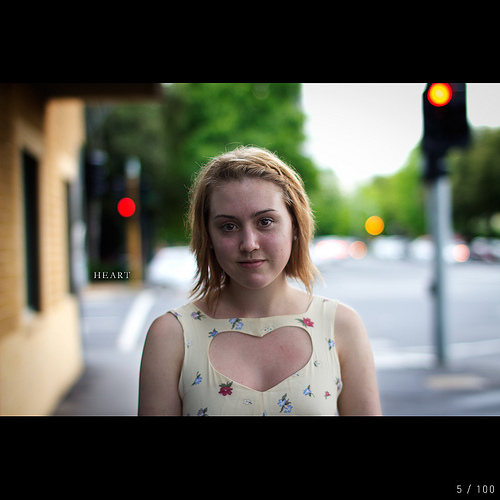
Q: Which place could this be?
A: It is a street.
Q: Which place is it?
A: It is a street.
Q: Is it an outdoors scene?
A: Yes, it is outdoors.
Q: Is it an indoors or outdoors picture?
A: It is outdoors.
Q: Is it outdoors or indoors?
A: It is outdoors.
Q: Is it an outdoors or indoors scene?
A: It is outdoors.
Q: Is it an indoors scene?
A: No, it is outdoors.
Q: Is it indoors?
A: No, it is outdoors.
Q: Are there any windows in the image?
A: Yes, there is a window.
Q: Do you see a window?
A: Yes, there is a window.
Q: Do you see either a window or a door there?
A: Yes, there is a window.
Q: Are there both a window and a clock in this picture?
A: No, there is a window but no clocks.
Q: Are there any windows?
A: Yes, there is a window.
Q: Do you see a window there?
A: Yes, there is a window.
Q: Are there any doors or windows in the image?
A: Yes, there is a window.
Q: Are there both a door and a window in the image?
A: No, there is a window but no doors.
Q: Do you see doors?
A: No, there are no doors.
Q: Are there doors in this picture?
A: No, there are no doors.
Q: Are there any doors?
A: No, there are no doors.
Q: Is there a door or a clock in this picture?
A: No, there are no doors or clocks.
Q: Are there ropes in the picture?
A: No, there are no ropes.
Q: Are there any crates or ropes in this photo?
A: No, there are no ropes or crates.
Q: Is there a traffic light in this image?
A: Yes, there is a traffic light.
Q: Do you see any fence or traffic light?
A: Yes, there is a traffic light.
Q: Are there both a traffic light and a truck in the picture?
A: No, there is a traffic light but no trucks.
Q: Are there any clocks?
A: No, there are no clocks.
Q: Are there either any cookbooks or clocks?
A: No, there are no clocks or cookbooks.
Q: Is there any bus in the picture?
A: No, there are no buses.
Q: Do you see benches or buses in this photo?
A: No, there are no buses or benches.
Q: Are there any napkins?
A: No, there are no napkins.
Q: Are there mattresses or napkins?
A: No, there are no napkins or mattresses.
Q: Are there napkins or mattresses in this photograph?
A: No, there are no napkins or mattresses.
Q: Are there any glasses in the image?
A: No, there are no glasses.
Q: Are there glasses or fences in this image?
A: No, there are no glasses or fences.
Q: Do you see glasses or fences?
A: No, there are no glasses or fences.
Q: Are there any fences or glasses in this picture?
A: No, there are no glasses or fences.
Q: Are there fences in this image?
A: No, there are no fences.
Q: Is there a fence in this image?
A: No, there are no fences.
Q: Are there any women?
A: Yes, there is a woman.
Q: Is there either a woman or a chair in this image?
A: Yes, there is a woman.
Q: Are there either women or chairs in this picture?
A: Yes, there is a woman.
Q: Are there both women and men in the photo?
A: No, there is a woman but no men.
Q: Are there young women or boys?
A: Yes, there is a young woman.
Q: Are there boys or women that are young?
A: Yes, the woman is young.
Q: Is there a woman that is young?
A: Yes, there is a young woman.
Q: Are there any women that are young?
A: Yes, there is a woman that is young.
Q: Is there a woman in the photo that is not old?
A: Yes, there is an young woman.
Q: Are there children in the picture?
A: No, there are no children.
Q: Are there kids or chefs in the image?
A: No, there are no kids or chefs.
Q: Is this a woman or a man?
A: This is a woman.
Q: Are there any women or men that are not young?
A: No, there is a woman but she is young.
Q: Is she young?
A: Yes, the woman is young.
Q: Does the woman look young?
A: Yes, the woman is young.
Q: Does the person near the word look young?
A: Yes, the woman is young.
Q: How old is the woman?
A: The woman is young.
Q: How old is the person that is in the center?
A: The woman is young.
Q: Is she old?
A: No, the woman is young.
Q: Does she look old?
A: No, the woman is young.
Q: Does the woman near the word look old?
A: No, the woman is young.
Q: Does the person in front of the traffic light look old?
A: No, the woman is young.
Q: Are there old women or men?
A: No, there is a woman but she is young.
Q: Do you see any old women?
A: No, there is a woman but she is young.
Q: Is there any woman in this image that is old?
A: No, there is a woman but she is young.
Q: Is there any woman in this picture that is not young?
A: No, there is a woman but she is young.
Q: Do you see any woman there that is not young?
A: No, there is a woman but she is young.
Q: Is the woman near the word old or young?
A: The woman is young.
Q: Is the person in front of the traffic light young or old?
A: The woman is young.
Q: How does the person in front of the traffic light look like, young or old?
A: The woman is young.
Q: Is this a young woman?
A: Yes, this is a young woman.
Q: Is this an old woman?
A: No, this is a young woman.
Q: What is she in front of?
A: The woman is in front of the traffic signal.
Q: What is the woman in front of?
A: The woman is in front of the traffic signal.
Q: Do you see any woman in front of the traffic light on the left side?
A: Yes, there is a woman in front of the traffic light.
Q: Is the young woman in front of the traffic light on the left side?
A: Yes, the woman is in front of the traffic signal.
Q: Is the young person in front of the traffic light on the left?
A: Yes, the woman is in front of the traffic signal.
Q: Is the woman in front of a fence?
A: No, the woman is in front of the traffic signal.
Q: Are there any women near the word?
A: Yes, there is a woman near the word.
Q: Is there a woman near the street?
A: Yes, there is a woman near the street.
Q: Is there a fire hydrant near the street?
A: No, there is a woman near the street.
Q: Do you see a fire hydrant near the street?
A: No, there is a woman near the street.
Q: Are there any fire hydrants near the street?
A: No, there is a woman near the street.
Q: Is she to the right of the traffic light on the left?
A: Yes, the woman is to the right of the traffic light.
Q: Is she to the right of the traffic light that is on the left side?
A: Yes, the woman is to the right of the traffic light.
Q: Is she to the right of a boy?
A: No, the woman is to the right of the traffic light.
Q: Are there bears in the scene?
A: No, there are no bears.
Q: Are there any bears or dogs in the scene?
A: No, there are no bears or dogs.